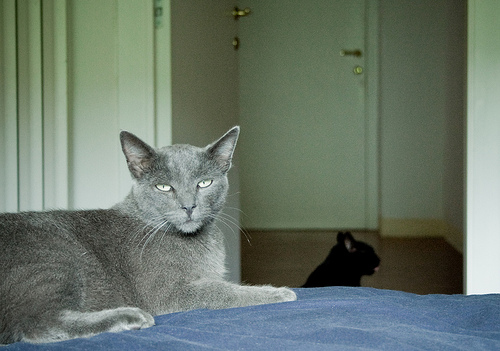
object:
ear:
[119, 130, 160, 181]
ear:
[204, 125, 241, 173]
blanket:
[0, 285, 500, 351]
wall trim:
[380, 219, 446, 237]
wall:
[387, 2, 461, 236]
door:
[237, 0, 378, 230]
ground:
[238, 224, 468, 294]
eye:
[198, 178, 214, 188]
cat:
[0, 124, 297, 344]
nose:
[180, 198, 196, 213]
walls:
[172, 0, 234, 132]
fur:
[25, 225, 160, 300]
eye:
[154, 182, 175, 192]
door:
[154, 0, 241, 283]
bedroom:
[0, 0, 500, 351]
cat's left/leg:
[12, 306, 156, 345]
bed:
[0, 285, 497, 350]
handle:
[339, 49, 361, 58]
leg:
[182, 275, 296, 310]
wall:
[0, 0, 171, 210]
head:
[118, 126, 239, 233]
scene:
[0, 0, 498, 349]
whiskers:
[206, 202, 254, 245]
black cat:
[301, 229, 383, 288]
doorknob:
[353, 66, 363, 75]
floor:
[248, 220, 467, 293]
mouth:
[173, 215, 207, 231]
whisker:
[120, 212, 172, 261]